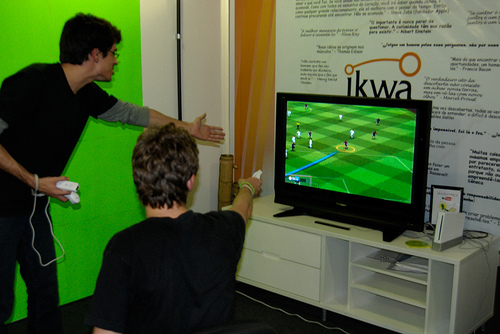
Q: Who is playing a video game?
A: Two men.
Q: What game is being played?
A: Soccer.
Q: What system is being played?
A: The Wii.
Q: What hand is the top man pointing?
A: Left hand.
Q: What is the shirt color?
A: Black.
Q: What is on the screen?
A: Game.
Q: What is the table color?
A: White.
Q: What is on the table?
A: Drawers.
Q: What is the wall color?
A: Green.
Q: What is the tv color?
A: Black.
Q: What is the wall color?
A: White.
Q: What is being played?
A: Video game.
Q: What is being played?
A: Video game.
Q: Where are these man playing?
A: In a room.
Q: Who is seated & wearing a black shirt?
A: A man.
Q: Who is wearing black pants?
A: A man.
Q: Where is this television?
A: On a stand.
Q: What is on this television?
A: A soccer game.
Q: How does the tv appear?
A: Turned on.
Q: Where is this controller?
A: In the hand of the man.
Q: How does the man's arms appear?
A: Extended.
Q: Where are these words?
A: On the wall.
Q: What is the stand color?
A: White.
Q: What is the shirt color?
A: Black.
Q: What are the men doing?
A: Playing.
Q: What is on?
A: The tv.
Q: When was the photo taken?
A: Daytime.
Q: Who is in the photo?
A: People.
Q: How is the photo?
A: Clear.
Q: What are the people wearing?
A: Clothes.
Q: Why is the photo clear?
A: The area lit.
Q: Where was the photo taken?
A: In the game room of an office.